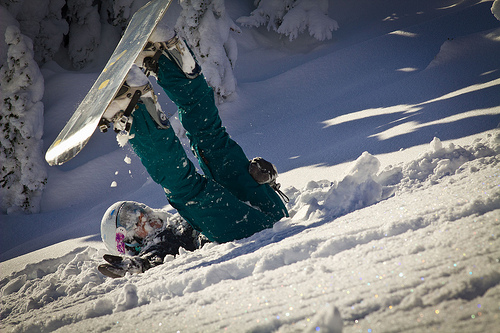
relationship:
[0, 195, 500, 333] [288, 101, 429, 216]
tracks on snow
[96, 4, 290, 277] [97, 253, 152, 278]
boarder wearing black mitten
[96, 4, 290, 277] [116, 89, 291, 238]
boarder wearing suit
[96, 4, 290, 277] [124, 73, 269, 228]
boarder has legs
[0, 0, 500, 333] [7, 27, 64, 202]
snow on tree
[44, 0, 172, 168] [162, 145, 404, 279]
board casting shadow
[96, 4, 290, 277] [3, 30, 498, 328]
boarder fallen on ground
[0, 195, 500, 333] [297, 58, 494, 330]
tracks in snow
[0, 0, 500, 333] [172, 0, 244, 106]
snow on tree branch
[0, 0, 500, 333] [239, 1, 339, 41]
snow on tree branch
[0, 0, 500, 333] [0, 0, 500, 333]
snow on snow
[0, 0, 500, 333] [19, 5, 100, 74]
snow on tree branch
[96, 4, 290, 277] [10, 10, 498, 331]
boarder on snow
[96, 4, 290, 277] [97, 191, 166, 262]
boarder wearing a hat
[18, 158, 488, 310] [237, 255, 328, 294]
field in snow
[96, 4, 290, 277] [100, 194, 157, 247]
boarder has googles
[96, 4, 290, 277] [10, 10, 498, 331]
boarder crashed in snow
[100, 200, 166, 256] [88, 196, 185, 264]
helmet on head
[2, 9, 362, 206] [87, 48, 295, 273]
trees behind person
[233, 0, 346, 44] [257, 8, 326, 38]
tree branch covered by snow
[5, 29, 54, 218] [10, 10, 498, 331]
tree branch covered by snow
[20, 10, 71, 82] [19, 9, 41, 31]
tree branch covered by snow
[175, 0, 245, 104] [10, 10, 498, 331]
branch covered by snow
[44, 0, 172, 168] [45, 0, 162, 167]
board has bottom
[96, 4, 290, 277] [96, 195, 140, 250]
boarder has helmet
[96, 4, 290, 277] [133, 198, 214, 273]
boarder has coat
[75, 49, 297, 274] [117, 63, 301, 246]
boarder has pants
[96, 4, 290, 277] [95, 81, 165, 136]
boarder has boots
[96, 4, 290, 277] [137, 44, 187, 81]
boarder has boots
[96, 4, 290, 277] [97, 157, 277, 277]
boarder has gloves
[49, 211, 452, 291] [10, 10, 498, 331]
tracks in snow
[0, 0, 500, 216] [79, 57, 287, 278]
trees behind boarder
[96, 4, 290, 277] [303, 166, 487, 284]
boarder has fallen in snow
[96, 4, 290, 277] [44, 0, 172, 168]
boarder playing with board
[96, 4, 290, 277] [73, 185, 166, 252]
boarder wearing helmet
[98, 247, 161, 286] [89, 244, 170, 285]
black mitten on hand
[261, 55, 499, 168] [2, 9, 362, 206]
shadow cast by trees